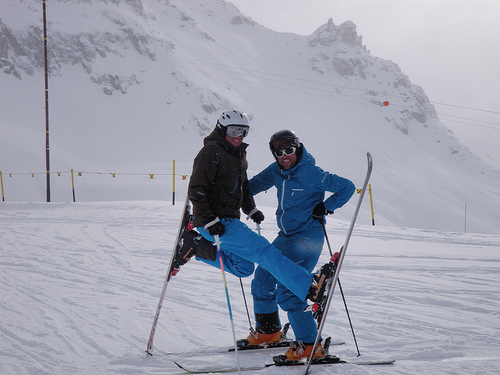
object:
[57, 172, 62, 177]
flag